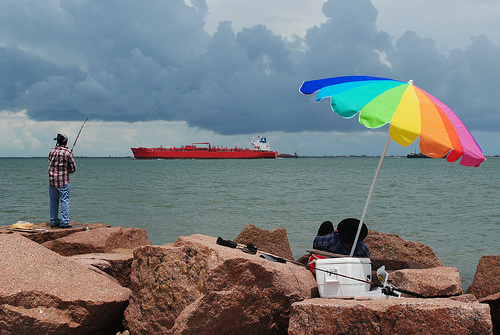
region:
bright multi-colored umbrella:
[300, 73, 485, 168]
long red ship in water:
[128, 138, 282, 160]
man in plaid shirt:
[44, 144, 79, 187]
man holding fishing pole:
[67, 115, 90, 156]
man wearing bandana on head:
[51, 130, 68, 147]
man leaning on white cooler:
[312, 254, 375, 299]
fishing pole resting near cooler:
[213, 234, 419, 298]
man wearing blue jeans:
[47, 179, 72, 224]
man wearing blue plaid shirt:
[313, 229, 368, 258]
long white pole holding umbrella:
[348, 133, 395, 256]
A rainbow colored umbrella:
[295, 68, 484, 187]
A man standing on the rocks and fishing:
[43, 114, 94, 225]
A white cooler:
[314, 263, 379, 296]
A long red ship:
[126, 136, 285, 163]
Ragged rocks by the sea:
[5, 217, 490, 334]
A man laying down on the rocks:
[310, 211, 375, 258]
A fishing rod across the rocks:
[218, 240, 426, 307]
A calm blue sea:
[3, 160, 498, 242]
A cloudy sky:
[6, 4, 339, 137]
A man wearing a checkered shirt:
[45, 135, 75, 185]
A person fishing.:
[45, 112, 98, 222]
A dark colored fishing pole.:
[65, 117, 91, 150]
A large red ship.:
[134, 133, 280, 168]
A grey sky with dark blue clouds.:
[3, 2, 498, 159]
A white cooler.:
[319, 257, 371, 297]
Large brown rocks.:
[0, 213, 499, 330]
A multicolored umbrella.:
[299, 75, 489, 168]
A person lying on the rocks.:
[308, 205, 370, 259]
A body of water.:
[2, 154, 497, 283]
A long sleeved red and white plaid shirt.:
[45, 147, 75, 187]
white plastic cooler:
[314, 255, 373, 300]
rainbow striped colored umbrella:
[298, 75, 487, 255]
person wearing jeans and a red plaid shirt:
[46, 131, 76, 229]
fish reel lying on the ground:
[215, 234, 426, 297]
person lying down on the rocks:
[313, 216, 371, 260]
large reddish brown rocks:
[0, 215, 499, 333]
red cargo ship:
[130, 135, 278, 161]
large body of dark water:
[0, 155, 499, 295]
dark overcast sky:
[1, 0, 498, 157]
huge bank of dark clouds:
[2, 0, 499, 135]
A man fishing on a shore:
[40, 122, 100, 224]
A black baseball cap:
[47, 126, 67, 143]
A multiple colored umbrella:
[291, 46, 486, 246]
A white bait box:
[307, 252, 372, 297]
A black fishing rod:
[257, 245, 423, 310]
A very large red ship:
[126, 130, 282, 170]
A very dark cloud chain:
[5, 20, 495, 117]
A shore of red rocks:
[7, 220, 497, 331]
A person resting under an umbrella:
[310, 215, 375, 260]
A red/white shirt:
[44, 145, 77, 189]